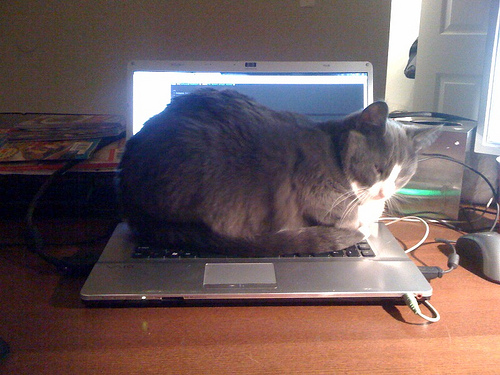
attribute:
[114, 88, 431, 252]
cat — big, grey , white 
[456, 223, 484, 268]
mouse — black, gray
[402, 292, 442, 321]
plug — green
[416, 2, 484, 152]
door — white, in the back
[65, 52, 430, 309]
laptop — grey, on, silver, Black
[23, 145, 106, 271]
cable — black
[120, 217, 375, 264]
keyboard — laptop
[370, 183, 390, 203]
nose — little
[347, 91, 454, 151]
ears — small, furry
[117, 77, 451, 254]
cat — gray, white, furry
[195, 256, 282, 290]
mouse pad — gray, laptop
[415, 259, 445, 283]
usb plug — gray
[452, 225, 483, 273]
mouse — black, silver, computer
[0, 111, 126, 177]
magazines — different colored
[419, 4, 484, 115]
door — white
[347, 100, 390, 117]
ear — furry, grey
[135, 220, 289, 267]
keys — black, computer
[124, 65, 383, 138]
screen — bright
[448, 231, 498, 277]
mouse — grey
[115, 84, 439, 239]
cat — grey, sitting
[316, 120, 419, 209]
face — furry, white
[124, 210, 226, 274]
tail — long, gray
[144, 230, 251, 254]
keys — black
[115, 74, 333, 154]
computer light — white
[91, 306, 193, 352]
desk — reflecting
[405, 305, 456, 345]
cord — white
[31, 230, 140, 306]
cord — black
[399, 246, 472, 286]
cord — black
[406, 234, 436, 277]
cord — usb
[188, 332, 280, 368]
desk — wooden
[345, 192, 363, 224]
whiskers — white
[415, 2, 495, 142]
door — white 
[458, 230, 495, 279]
mouse — grey 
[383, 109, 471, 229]
shredder — grey 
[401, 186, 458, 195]
light — green  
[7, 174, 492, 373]
table — wood 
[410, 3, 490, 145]
door — white 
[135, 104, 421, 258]
cat — GREY, WHITE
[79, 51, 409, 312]
computer — LAPTOP